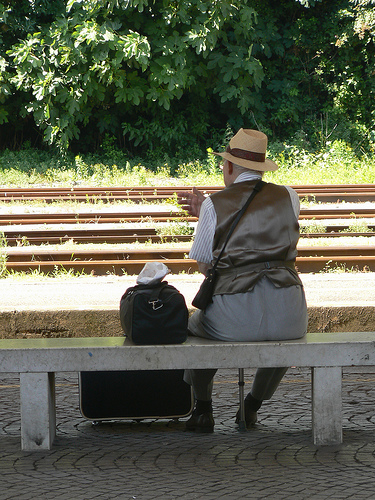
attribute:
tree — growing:
[13, 4, 271, 142]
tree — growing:
[271, 0, 373, 135]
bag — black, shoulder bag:
[190, 268, 216, 308]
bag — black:
[119, 284, 193, 343]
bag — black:
[77, 366, 192, 422]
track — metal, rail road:
[0, 247, 189, 274]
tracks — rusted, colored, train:
[1, 188, 372, 274]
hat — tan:
[205, 127, 281, 170]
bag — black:
[118, 280, 190, 343]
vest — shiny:
[208, 179, 298, 292]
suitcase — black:
[119, 277, 191, 347]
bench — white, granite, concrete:
[7, 334, 370, 458]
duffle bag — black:
[115, 279, 193, 347]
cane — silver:
[220, 357, 287, 436]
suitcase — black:
[74, 336, 199, 418]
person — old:
[186, 129, 312, 348]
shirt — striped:
[183, 180, 311, 298]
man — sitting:
[180, 127, 307, 429]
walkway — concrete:
[0, 366, 373, 496]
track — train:
[1, 243, 373, 276]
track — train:
[1, 229, 374, 245]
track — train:
[1, 210, 373, 219]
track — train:
[1, 182, 373, 206]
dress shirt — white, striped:
[189, 202, 212, 262]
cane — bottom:
[235, 369, 245, 429]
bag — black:
[103, 259, 225, 360]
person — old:
[184, 127, 307, 434]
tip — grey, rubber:
[237, 421, 249, 432]